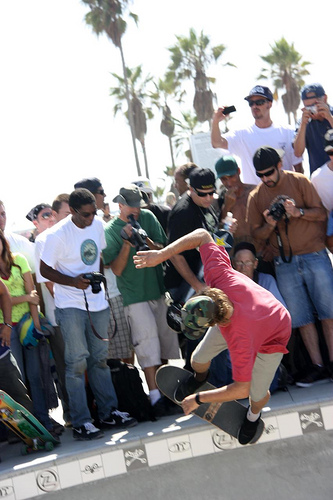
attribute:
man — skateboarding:
[132, 225, 293, 450]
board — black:
[154, 361, 270, 457]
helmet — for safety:
[176, 295, 221, 337]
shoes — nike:
[68, 413, 141, 440]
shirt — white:
[34, 210, 121, 316]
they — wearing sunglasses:
[0, 53, 332, 489]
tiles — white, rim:
[0, 372, 332, 499]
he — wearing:
[131, 221, 301, 463]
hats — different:
[23, 69, 331, 252]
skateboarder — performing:
[112, 210, 296, 452]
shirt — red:
[197, 232, 296, 387]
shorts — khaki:
[184, 318, 286, 406]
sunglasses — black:
[194, 188, 218, 197]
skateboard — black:
[153, 362, 264, 446]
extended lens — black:
[91, 279, 101, 296]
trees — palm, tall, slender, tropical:
[81, 0, 315, 186]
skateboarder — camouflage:
[159, 226, 304, 436]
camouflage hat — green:
[174, 293, 217, 341]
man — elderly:
[232, 249, 285, 308]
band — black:
[191, 386, 202, 402]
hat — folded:
[111, 185, 148, 207]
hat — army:
[180, 295, 217, 341]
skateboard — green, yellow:
[1, 389, 61, 459]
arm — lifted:
[127, 224, 232, 269]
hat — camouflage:
[179, 296, 217, 335]